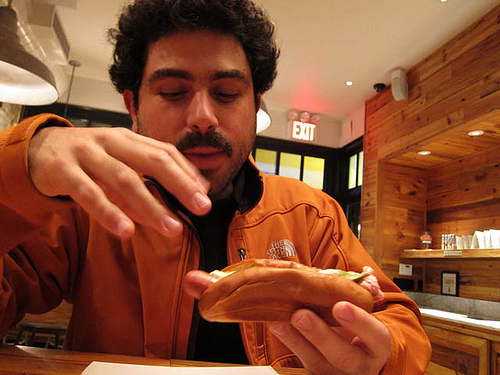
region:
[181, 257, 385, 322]
a hot dog and bun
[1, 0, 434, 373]
a man holding a hot dog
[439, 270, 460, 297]
a picture with black frame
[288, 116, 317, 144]
an exit sign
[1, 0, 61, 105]
a white hanging light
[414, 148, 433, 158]
a small round recessed light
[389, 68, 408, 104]
a white light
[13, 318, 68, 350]
the top of a stool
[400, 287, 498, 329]
a mottled countertop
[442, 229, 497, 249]
a row of folded cards standing on edge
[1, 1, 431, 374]
A man holding a hotdog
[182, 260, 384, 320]
A hotdog on a bun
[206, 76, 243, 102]
A man's left eye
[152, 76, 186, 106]
A man's right eye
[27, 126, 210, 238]
A man's right hand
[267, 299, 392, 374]
A ,man's left hand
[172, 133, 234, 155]
A man's mustache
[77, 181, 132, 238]
A man's right pinky finger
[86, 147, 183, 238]
A man's right ring finger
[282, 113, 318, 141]
An exit sign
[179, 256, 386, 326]
A hot dog on a bun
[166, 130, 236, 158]
A black mustache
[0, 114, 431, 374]
An orange jacket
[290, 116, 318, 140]
An exit sign above door.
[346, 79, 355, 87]
Small round light on ceiling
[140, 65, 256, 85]
A pair of black eye brows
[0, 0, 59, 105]
A silver light fixture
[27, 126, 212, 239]
Right hand of man.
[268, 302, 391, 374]
Left hand of man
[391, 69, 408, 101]
A grey speaker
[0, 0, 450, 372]
man close beside a table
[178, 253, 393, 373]
a hotdog-like food in man's hand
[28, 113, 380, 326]
man's right hand hovering above food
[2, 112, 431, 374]
man is wearing an orange jacket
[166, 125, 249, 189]
man has facial hair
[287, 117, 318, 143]
an internally illuminated EXIT sign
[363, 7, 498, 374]
wooden structure with a shelf against a wall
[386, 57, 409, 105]
a small white speaker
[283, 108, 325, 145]
three emergency lights above sign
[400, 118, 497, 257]
recessed lighting above shelf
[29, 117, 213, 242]
the hand of a man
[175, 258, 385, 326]
a hot dog sandwich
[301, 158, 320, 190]
a large window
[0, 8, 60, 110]
part of a lamp shade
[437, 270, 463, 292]
a black picture frame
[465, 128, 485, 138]
a ceiling light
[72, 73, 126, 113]
part of a white ceiling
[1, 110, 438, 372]
a man's brown jacket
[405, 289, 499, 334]
a granite counter top